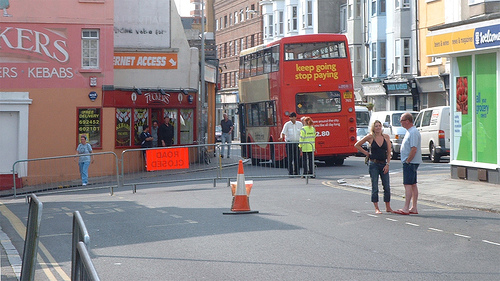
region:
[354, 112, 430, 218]
Woman in black top next to man in shorts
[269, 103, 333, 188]
Woman in yellow vest next to man in black hat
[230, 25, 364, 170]
Red double decker bus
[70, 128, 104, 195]
woman in blue shirt and pants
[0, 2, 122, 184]
Woman in blue walking past pink restaurant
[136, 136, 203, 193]
road closed sign on barricade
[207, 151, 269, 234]
Orange caution cone in street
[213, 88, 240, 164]
Man in dark blue shirt and light blue pants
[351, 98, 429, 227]
Woman and man standing in the street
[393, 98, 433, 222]
Man in white shirt and blue shorts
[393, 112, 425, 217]
A man wearing a gray t shirt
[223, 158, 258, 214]
An orange and white traffic cone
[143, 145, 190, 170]
A bright orange sign on a fence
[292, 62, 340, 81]
Yellow writing on the back of a bus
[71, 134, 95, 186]
A woman walking down the street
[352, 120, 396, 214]
A woman wearing a black blouse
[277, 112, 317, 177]
Two people standing on the street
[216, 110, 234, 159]
A man walking on the sidewalk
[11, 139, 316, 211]
Metal segments of temporary fencing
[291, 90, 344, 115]
The rear window on a bus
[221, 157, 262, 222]
Orange and white cone in road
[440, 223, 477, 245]
white line painted on pavement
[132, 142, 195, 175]
Back of orange road closed sign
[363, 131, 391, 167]
woman wearing black shirt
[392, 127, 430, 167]
man wearing white shirt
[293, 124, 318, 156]
woman wearing yellow safety shirt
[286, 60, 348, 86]
yellow sign on back of bus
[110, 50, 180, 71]
part of internet access sign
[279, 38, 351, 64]
Rear upper window of bus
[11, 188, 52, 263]
metal barrier on street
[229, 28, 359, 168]
a red double decker bus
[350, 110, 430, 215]
two people talking in the street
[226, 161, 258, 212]
an orange cone in the middle of the street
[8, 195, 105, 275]
metal fence railing on the street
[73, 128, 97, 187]
person walking on the side walk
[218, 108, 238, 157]
a man walking on the sidewalk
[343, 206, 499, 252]
white lines on the street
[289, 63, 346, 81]
yellow text on the bus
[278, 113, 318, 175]
two people standing next to railing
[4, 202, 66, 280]
yellow lines painted on the road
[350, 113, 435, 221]
A man and woman talking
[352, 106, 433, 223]
People talking in the street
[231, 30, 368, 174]
Red bus driving down rode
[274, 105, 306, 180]
Man leaning against medal fence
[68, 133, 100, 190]
Woman walking across the road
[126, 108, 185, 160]
Three men standing at the door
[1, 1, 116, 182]
Building is peach and pink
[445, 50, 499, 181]
Green window on building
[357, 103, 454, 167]
Cars parked on side of street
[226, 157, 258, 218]
Orange and white caution cone